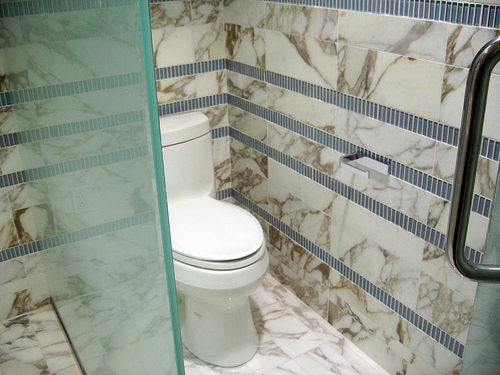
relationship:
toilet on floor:
[169, 133, 288, 308] [298, 306, 333, 351]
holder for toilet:
[341, 155, 381, 182] [169, 133, 288, 308]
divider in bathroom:
[129, 40, 197, 162] [32, 22, 451, 358]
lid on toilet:
[176, 210, 238, 248] [169, 133, 288, 308]